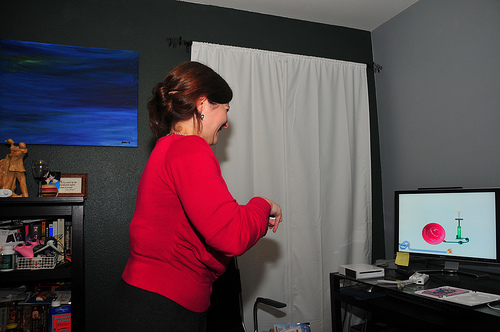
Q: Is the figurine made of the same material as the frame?
A: Yes, both the figurine and the frame are made of wood.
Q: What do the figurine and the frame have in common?
A: The material, both the figurine and the frame are wooden.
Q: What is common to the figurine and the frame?
A: The material, both the figurine and the frame are wooden.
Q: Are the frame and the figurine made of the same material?
A: Yes, both the frame and the figurine are made of wood.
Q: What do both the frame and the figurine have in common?
A: The material, both the frame and the figurine are wooden.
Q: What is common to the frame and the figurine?
A: The material, both the frame and the figurine are wooden.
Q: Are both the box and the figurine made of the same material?
A: No, the box is made of plastic and the figurine is made of wood.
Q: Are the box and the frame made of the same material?
A: No, the box is made of plastic and the frame is made of wood.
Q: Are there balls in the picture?
A: Yes, there is a ball.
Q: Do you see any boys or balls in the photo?
A: Yes, there is a ball.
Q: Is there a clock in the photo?
A: No, there are no clocks.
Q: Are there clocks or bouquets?
A: No, there are no clocks or bouquets.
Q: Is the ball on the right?
A: Yes, the ball is on the right of the image.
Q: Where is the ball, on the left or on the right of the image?
A: The ball is on the right of the image.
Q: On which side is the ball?
A: The ball is on the right of the image.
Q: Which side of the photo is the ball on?
A: The ball is on the right of the image.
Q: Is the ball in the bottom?
A: Yes, the ball is in the bottom of the image.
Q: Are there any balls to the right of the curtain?
A: Yes, there is a ball to the right of the curtain.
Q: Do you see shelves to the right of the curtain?
A: No, there is a ball to the right of the curtain.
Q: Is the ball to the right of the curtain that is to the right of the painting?
A: Yes, the ball is to the right of the curtain.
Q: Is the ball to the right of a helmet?
A: No, the ball is to the right of the curtain.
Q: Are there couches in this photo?
A: No, there are no couches.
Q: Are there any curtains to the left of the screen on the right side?
A: Yes, there is a curtain to the left of the screen.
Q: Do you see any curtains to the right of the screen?
A: No, the curtain is to the left of the screen.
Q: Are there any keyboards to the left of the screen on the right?
A: No, there is a curtain to the left of the screen.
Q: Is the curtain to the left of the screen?
A: Yes, the curtain is to the left of the screen.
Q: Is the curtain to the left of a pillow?
A: No, the curtain is to the left of the screen.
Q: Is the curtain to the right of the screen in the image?
A: No, the curtain is to the left of the screen.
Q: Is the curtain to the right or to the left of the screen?
A: The curtain is to the left of the screen.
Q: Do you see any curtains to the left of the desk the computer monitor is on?
A: Yes, there is a curtain to the left of the desk.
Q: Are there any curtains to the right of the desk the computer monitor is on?
A: No, the curtain is to the left of the desk.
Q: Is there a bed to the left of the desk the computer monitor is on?
A: No, there is a curtain to the left of the desk.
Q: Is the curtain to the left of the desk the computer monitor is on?
A: Yes, the curtain is to the left of the desk.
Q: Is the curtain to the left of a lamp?
A: No, the curtain is to the left of the desk.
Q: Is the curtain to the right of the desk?
A: No, the curtain is to the left of the desk.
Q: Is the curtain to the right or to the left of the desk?
A: The curtain is to the left of the desk.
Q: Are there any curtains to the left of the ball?
A: Yes, there is a curtain to the left of the ball.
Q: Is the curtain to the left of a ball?
A: Yes, the curtain is to the left of a ball.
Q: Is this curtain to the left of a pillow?
A: No, the curtain is to the left of a ball.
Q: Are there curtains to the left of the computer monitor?
A: Yes, there is a curtain to the left of the computer monitor.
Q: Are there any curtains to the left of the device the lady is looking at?
A: Yes, there is a curtain to the left of the computer monitor.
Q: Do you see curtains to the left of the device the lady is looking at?
A: Yes, there is a curtain to the left of the computer monitor.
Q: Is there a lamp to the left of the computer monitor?
A: No, there is a curtain to the left of the computer monitor.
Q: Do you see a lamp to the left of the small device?
A: No, there is a curtain to the left of the computer monitor.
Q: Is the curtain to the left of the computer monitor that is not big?
A: Yes, the curtain is to the left of the computer monitor.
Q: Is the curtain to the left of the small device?
A: Yes, the curtain is to the left of the computer monitor.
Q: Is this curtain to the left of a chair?
A: No, the curtain is to the left of the computer monitor.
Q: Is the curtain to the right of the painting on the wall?
A: Yes, the curtain is to the right of the painting.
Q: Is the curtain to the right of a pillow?
A: No, the curtain is to the right of the painting.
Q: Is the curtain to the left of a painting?
A: No, the curtain is to the right of a painting.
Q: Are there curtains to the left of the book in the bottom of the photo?
A: Yes, there is a curtain to the left of the book.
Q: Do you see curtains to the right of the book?
A: No, the curtain is to the left of the book.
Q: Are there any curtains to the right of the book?
A: No, the curtain is to the left of the book.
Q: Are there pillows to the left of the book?
A: No, there is a curtain to the left of the book.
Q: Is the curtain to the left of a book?
A: Yes, the curtain is to the left of a book.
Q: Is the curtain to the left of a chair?
A: No, the curtain is to the left of a book.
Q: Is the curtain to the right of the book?
A: No, the curtain is to the left of the book.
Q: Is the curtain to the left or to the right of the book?
A: The curtain is to the left of the book.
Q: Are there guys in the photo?
A: No, there are no guys.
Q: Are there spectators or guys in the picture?
A: No, there are no guys or spectators.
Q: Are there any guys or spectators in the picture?
A: No, there are no guys or spectators.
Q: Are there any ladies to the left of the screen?
A: Yes, there is a lady to the left of the screen.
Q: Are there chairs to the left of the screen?
A: No, there is a lady to the left of the screen.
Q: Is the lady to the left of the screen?
A: Yes, the lady is to the left of the screen.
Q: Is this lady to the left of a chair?
A: No, the lady is to the left of the screen.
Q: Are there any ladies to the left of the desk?
A: Yes, there is a lady to the left of the desk.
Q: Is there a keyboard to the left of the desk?
A: No, there is a lady to the left of the desk.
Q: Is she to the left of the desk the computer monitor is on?
A: Yes, the lady is to the left of the desk.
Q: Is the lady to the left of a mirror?
A: No, the lady is to the left of the desk.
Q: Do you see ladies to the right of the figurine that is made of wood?
A: Yes, there is a lady to the right of the figurine.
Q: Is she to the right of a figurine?
A: Yes, the lady is to the right of a figurine.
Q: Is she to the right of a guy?
A: No, the lady is to the right of a figurine.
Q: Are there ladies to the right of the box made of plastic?
A: Yes, there is a lady to the right of the box.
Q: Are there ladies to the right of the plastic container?
A: Yes, there is a lady to the right of the box.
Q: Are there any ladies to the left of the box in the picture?
A: No, the lady is to the right of the box.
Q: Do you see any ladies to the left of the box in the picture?
A: No, the lady is to the right of the box.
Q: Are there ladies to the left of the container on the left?
A: No, the lady is to the right of the box.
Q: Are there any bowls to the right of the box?
A: No, there is a lady to the right of the box.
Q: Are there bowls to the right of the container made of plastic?
A: No, there is a lady to the right of the box.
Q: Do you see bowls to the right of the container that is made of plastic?
A: No, there is a lady to the right of the box.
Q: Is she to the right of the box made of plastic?
A: Yes, the lady is to the right of the box.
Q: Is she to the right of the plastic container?
A: Yes, the lady is to the right of the box.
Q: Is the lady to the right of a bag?
A: No, the lady is to the right of the box.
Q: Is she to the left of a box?
A: No, the lady is to the right of a box.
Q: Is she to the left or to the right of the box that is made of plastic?
A: The lady is to the right of the box.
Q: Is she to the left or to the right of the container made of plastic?
A: The lady is to the right of the box.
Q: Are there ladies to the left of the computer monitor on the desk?
A: Yes, there is a lady to the left of the computer monitor.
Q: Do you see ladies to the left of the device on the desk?
A: Yes, there is a lady to the left of the computer monitor.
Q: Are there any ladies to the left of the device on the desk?
A: Yes, there is a lady to the left of the computer monitor.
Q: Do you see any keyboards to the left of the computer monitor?
A: No, there is a lady to the left of the computer monitor.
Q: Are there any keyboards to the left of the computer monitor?
A: No, there is a lady to the left of the computer monitor.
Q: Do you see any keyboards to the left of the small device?
A: No, there is a lady to the left of the computer monitor.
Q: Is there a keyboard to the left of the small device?
A: No, there is a lady to the left of the computer monitor.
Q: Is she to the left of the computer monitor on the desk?
A: Yes, the lady is to the left of the computer monitor.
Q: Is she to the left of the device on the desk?
A: Yes, the lady is to the left of the computer monitor.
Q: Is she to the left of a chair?
A: No, the lady is to the left of the computer monitor.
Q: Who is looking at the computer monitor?
A: The lady is looking at the computer monitor.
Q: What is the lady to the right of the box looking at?
A: The lady is looking at the computer monitor.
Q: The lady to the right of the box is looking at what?
A: The lady is looking at the computer monitor.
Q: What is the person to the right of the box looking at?
A: The lady is looking at the computer monitor.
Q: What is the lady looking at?
A: The lady is looking at the computer monitor.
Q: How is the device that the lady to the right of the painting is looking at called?
A: The device is a computer monitor.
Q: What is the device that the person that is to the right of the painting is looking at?
A: The device is a computer monitor.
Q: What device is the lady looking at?
A: The lady is looking at the computer monitor.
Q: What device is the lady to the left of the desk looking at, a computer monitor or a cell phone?
A: The lady is looking at a computer monitor.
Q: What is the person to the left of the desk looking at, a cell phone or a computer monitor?
A: The lady is looking at a computer monitor.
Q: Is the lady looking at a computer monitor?
A: Yes, the lady is looking at a computer monitor.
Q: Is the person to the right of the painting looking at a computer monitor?
A: Yes, the lady is looking at a computer monitor.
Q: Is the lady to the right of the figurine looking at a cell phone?
A: No, the lady is looking at a computer monitor.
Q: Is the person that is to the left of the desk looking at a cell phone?
A: No, the lady is looking at a computer monitor.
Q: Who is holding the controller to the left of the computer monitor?
A: The lady is holding the controller.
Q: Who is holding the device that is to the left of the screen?
A: The lady is holding the controller.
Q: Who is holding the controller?
A: The lady is holding the controller.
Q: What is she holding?
A: The lady is holding the controller.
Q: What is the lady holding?
A: The lady is holding the controller.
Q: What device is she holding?
A: The lady is holding the controller.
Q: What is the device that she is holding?
A: The device is a controller.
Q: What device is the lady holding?
A: The lady is holding the controller.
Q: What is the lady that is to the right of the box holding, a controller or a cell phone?
A: The lady is holding a controller.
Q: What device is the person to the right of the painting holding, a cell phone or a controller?
A: The lady is holding a controller.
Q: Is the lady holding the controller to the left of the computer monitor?
A: Yes, the lady is holding the controller.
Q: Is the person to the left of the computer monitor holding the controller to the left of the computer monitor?
A: Yes, the lady is holding the controller.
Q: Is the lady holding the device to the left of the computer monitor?
A: Yes, the lady is holding the controller.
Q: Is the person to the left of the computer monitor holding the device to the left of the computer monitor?
A: Yes, the lady is holding the controller.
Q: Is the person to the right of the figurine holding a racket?
A: No, the lady is holding the controller.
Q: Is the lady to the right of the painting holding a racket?
A: No, the lady is holding the controller.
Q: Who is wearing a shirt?
A: The lady is wearing a shirt.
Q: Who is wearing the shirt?
A: The lady is wearing a shirt.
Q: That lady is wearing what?
A: The lady is wearing a shirt.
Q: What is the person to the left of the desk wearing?
A: The lady is wearing a shirt.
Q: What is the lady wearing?
A: The lady is wearing a shirt.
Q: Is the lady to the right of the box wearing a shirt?
A: Yes, the lady is wearing a shirt.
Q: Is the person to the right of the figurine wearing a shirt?
A: Yes, the lady is wearing a shirt.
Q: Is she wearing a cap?
A: No, the lady is wearing a shirt.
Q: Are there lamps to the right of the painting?
A: No, there is a lady to the right of the painting.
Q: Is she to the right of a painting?
A: Yes, the lady is to the right of a painting.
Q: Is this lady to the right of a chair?
A: No, the lady is to the right of a painting.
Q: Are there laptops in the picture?
A: No, there are no laptops.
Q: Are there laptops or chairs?
A: No, there are no laptops or chairs.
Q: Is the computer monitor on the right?
A: Yes, the computer monitor is on the right of the image.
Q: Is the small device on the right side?
A: Yes, the computer monitor is on the right of the image.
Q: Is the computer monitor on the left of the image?
A: No, the computer monitor is on the right of the image.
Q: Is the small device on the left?
A: No, the computer monitor is on the right of the image.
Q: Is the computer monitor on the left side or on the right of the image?
A: The computer monitor is on the right of the image.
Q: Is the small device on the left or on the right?
A: The computer monitor is on the right of the image.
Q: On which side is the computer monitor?
A: The computer monitor is on the right of the image.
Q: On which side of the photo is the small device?
A: The computer monitor is on the right of the image.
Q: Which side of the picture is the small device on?
A: The computer monitor is on the right of the image.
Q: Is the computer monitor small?
A: Yes, the computer monitor is small.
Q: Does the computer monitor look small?
A: Yes, the computer monitor is small.